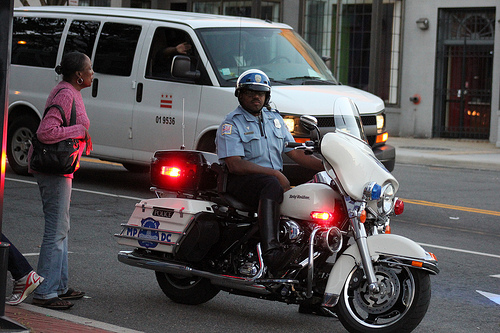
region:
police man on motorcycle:
[136, 63, 425, 325]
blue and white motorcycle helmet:
[227, 65, 276, 120]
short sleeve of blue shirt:
[215, 116, 245, 165]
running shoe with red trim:
[6, 270, 42, 307]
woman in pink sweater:
[31, 55, 100, 307]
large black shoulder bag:
[26, 81, 86, 179]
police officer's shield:
[270, 116, 283, 132]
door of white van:
[125, 16, 200, 153]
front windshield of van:
[182, 13, 341, 89]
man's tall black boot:
[253, 192, 303, 275]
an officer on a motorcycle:
[116, 65, 459, 315]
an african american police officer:
[206, 52, 327, 290]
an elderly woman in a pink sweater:
[33, 35, 130, 320]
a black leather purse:
[22, 82, 94, 190]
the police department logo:
[104, 206, 202, 261]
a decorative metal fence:
[424, 35, 486, 150]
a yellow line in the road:
[406, 183, 490, 239]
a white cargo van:
[0, 12, 420, 204]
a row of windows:
[3, 11, 150, 83]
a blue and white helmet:
[223, 63, 287, 118]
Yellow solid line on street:
[426, 191, 498, 212]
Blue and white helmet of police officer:
[234, 67, 273, 84]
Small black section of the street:
[419, 167, 495, 199]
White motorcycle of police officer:
[123, 139, 424, 307]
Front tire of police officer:
[333, 260, 437, 331]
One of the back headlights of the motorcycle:
[148, 145, 216, 192]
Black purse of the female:
[34, 141, 76, 171]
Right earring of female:
[73, 77, 86, 87]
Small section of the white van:
[95, 11, 219, 61]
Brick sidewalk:
[29, 317, 62, 332]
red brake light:
[147, 154, 201, 189]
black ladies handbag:
[42, 86, 82, 179]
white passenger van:
[21, 6, 390, 194]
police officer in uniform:
[207, 65, 300, 255]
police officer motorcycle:
[133, 111, 458, 331]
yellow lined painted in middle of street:
[405, 183, 494, 253]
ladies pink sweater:
[27, 73, 93, 184]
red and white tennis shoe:
[7, 259, 47, 310]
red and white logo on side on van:
[148, 86, 186, 113]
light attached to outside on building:
[408, 8, 438, 45]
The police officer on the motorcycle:
[112, 62, 442, 332]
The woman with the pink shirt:
[29, 47, 97, 317]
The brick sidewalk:
[0, 298, 140, 330]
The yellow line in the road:
[78, 153, 498, 219]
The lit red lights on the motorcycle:
[160, 163, 340, 229]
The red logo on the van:
[157, 89, 174, 111]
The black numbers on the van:
[150, 111, 179, 128]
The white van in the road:
[2, 5, 398, 200]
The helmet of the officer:
[232, 67, 277, 99]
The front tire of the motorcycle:
[322, 233, 443, 330]